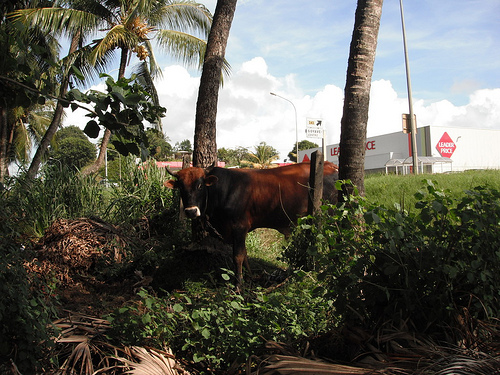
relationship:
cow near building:
[171, 163, 346, 247] [383, 115, 486, 169]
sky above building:
[233, 20, 335, 116] [383, 115, 486, 169]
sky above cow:
[233, 20, 335, 116] [171, 163, 346, 247]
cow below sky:
[171, 163, 346, 247] [233, 20, 335, 116]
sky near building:
[233, 20, 335, 116] [383, 115, 486, 169]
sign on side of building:
[432, 124, 465, 162] [295, 119, 484, 178]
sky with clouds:
[34, 2, 479, 112] [15, 43, 484, 173]